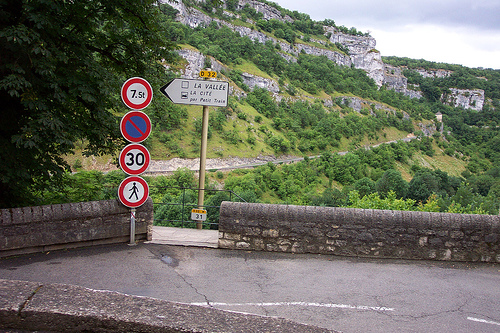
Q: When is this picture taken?
A: Daytime.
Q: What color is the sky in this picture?
A: Blue.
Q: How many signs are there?
A: Eight.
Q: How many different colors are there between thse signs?
A: Five.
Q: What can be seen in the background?
A: Ruins.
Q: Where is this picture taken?
A: On a Hillside.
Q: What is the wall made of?
A: Stone.